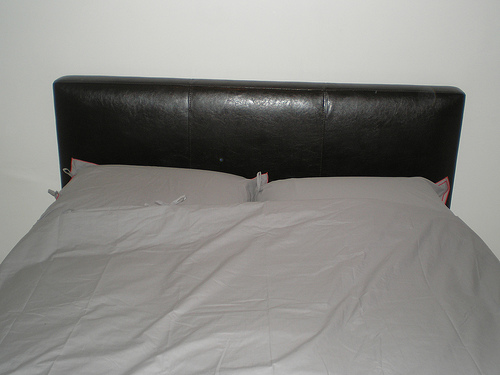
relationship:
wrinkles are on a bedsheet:
[141, 221, 256, 374] [2, 201, 500, 374]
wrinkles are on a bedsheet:
[265, 217, 451, 374] [2, 201, 500, 374]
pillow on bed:
[60, 157, 260, 213] [0, 76, 499, 374]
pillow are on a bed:
[258, 175, 450, 210] [0, 76, 499, 374]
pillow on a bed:
[60, 157, 260, 213] [0, 76, 499, 374]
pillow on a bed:
[258, 175, 450, 210] [0, 76, 499, 374]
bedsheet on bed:
[2, 201, 500, 374] [0, 76, 499, 374]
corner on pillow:
[71, 158, 89, 170] [60, 157, 260, 213]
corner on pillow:
[436, 176, 453, 194] [258, 175, 450, 210]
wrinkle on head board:
[327, 102, 335, 120] [53, 75, 465, 217]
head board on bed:
[53, 75, 465, 217] [0, 76, 499, 374]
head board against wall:
[53, 75, 465, 217] [1, 0, 498, 267]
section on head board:
[54, 79, 192, 182] [53, 75, 465, 217]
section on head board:
[188, 79, 328, 180] [53, 75, 465, 217]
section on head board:
[324, 82, 465, 213] [53, 75, 465, 217]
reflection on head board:
[224, 87, 317, 114] [53, 75, 465, 217]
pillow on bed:
[258, 175, 450, 210] [0, 76, 499, 374]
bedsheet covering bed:
[2, 201, 500, 374] [0, 76, 499, 374]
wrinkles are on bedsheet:
[265, 217, 451, 374] [2, 201, 500, 374]